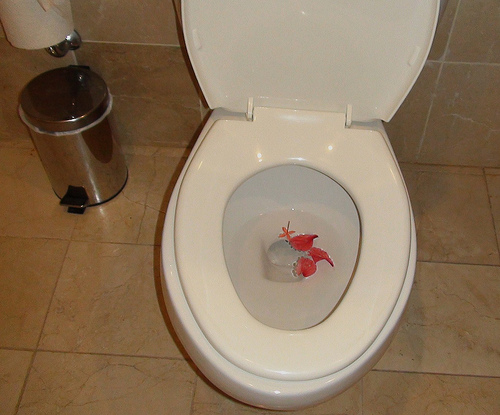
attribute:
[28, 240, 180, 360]
floor tile — brown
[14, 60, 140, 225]
trash can — silver, foot-pedal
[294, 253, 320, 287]
leaf — small, red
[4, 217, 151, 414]
floor — square-tile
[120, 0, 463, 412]
toilet — paper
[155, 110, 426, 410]
toilet bowl — white, porcelin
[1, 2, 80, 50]
toilet paper — roll 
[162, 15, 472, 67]
lid — up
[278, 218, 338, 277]
flower petals — pink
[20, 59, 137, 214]
can — trash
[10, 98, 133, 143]
bag — white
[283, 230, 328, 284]
petals — pink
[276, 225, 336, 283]
petals — flower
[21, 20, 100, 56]
holder — toilet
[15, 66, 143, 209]
trash can — silver, chrome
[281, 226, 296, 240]
leaf — red, small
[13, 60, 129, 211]
trash can — metal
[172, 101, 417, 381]
seat — toilet